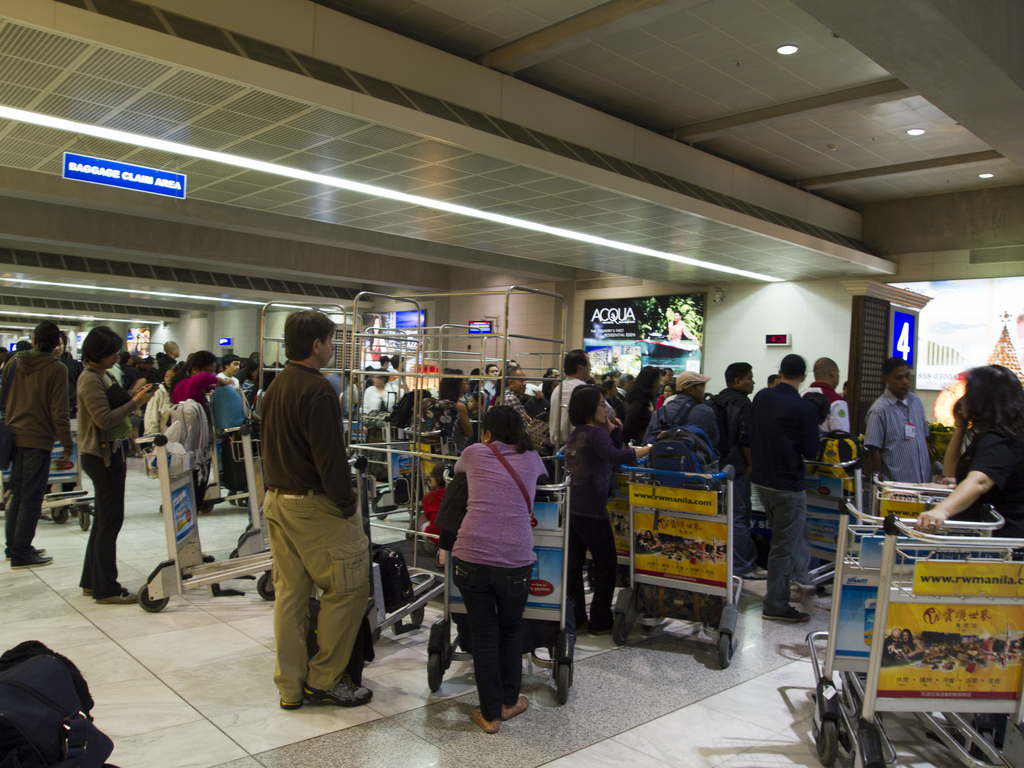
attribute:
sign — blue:
[44, 148, 213, 200]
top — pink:
[439, 422, 582, 587]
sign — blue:
[44, 137, 232, 243]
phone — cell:
[135, 366, 170, 431]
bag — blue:
[9, 619, 159, 762]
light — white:
[22, 85, 816, 328]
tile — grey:
[534, 629, 710, 746]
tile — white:
[31, 536, 338, 759]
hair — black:
[463, 398, 546, 453]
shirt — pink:
[444, 437, 566, 595]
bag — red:
[407, 459, 487, 544]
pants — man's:
[258, 482, 379, 716]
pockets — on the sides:
[327, 532, 371, 587]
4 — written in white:
[893, 318, 919, 366]